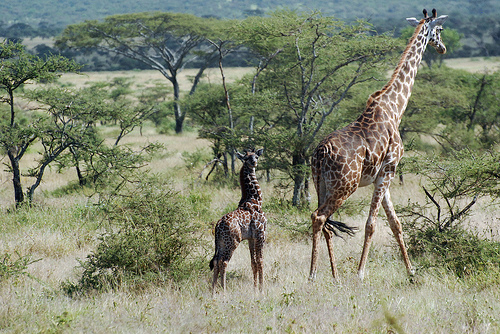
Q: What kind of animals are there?
A: Giraffes.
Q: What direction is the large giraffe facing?
A: Right.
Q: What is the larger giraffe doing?
A: Walking.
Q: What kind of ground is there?
A: Grass.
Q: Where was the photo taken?
A: In a field.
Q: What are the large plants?
A: Trees.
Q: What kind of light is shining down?
A: Sunlight.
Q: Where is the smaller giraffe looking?
A: At the camera.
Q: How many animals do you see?
A: Two.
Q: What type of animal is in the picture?
A: A giraffe.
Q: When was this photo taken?
A: Looks like in the day.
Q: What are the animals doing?
A: Walking around.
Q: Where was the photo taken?
A: In a field.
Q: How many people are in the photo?
A: There aren't any.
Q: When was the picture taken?
A: During the day.